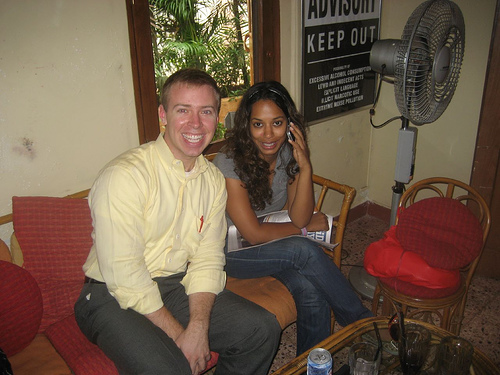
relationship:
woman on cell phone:
[217, 80, 372, 351] [285, 122, 295, 144]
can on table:
[306, 345, 332, 374] [267, 313, 496, 374]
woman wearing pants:
[217, 80, 372, 351] [223, 234, 369, 356]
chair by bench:
[365, 173, 492, 341] [2, 168, 355, 365]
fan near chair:
[369, 5, 466, 237] [365, 173, 492, 341]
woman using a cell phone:
[217, 80, 372, 351] [285, 122, 295, 144]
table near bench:
[267, 313, 496, 374] [2, 168, 355, 365]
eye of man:
[175, 106, 192, 113] [73, 68, 282, 367]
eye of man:
[200, 109, 215, 114] [73, 68, 282, 367]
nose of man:
[188, 110, 203, 127] [73, 68, 282, 367]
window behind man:
[148, 3, 257, 143] [73, 68, 282, 367]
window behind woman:
[148, 3, 257, 143] [217, 80, 372, 351]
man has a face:
[73, 68, 282, 367] [168, 81, 219, 155]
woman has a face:
[217, 80, 372, 351] [250, 98, 288, 154]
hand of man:
[175, 320, 213, 371] [73, 68, 282, 367]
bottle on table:
[439, 335, 472, 373] [267, 313, 496, 374]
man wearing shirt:
[73, 68, 282, 367] [81, 135, 228, 314]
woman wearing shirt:
[217, 80, 372, 351] [216, 143, 296, 253]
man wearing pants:
[73, 68, 282, 367] [76, 276, 282, 369]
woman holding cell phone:
[217, 80, 372, 351] [285, 122, 295, 144]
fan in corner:
[369, 5, 466, 237] [278, 3, 495, 221]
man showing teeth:
[73, 68, 282, 367] [182, 132, 206, 144]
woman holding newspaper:
[217, 80, 372, 351] [228, 210, 337, 250]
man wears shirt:
[73, 68, 282, 367] [81, 135, 228, 314]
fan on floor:
[369, 5, 466, 237] [273, 205, 497, 368]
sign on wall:
[303, 0, 384, 119] [280, 3, 367, 215]